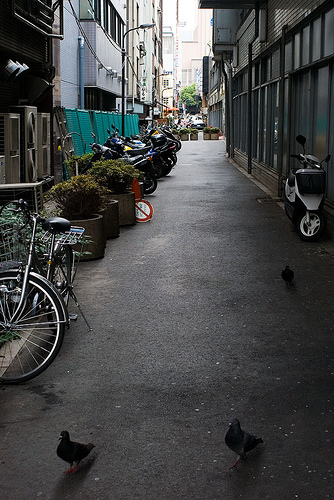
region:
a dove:
[189, 398, 291, 497]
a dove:
[223, 330, 320, 470]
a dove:
[186, 341, 257, 483]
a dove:
[226, 326, 266, 471]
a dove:
[219, 415, 265, 480]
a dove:
[209, 351, 249, 495]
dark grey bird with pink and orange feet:
[40, 416, 109, 484]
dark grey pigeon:
[36, 415, 117, 477]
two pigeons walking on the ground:
[46, 410, 279, 476]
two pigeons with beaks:
[46, 398, 273, 486]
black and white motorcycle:
[274, 133, 332, 249]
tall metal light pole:
[117, 13, 162, 171]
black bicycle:
[0, 205, 101, 389]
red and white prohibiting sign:
[132, 194, 156, 227]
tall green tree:
[180, 79, 204, 123]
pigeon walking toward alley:
[267, 249, 301, 300]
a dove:
[224, 439, 297, 498]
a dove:
[234, 381, 261, 493]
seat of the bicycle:
[47, 218, 66, 233]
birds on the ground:
[51, 421, 290, 462]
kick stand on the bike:
[66, 293, 101, 329]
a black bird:
[276, 264, 298, 290]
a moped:
[273, 156, 328, 237]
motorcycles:
[109, 122, 150, 160]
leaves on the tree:
[182, 88, 196, 108]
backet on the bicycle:
[2, 228, 19, 265]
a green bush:
[55, 183, 97, 210]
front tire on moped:
[298, 214, 325, 237]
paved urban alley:
[1, 137, 332, 495]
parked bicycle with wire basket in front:
[0, 198, 94, 381]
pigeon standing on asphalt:
[53, 427, 98, 473]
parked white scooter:
[277, 149, 332, 236]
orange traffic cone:
[130, 175, 144, 201]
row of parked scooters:
[90, 124, 181, 193]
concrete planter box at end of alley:
[188, 126, 199, 140]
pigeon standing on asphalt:
[220, 415, 266, 470]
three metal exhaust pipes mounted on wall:
[5, 58, 29, 76]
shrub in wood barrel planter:
[43, 174, 105, 261]